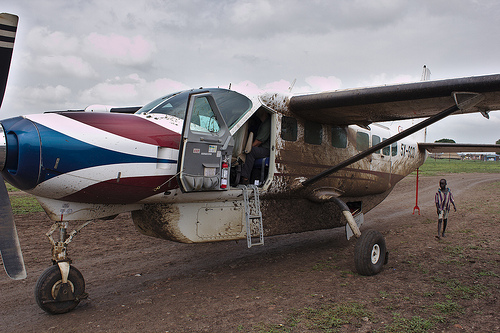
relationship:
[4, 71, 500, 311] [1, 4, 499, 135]
plane under sky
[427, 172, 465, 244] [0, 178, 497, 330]
boy on ground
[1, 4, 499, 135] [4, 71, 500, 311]
sky above plane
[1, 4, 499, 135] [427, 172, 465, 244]
sky above boy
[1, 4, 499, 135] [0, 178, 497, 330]
sky above ground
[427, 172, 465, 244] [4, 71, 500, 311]
boy beside plane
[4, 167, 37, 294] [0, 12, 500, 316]
propellers of plane